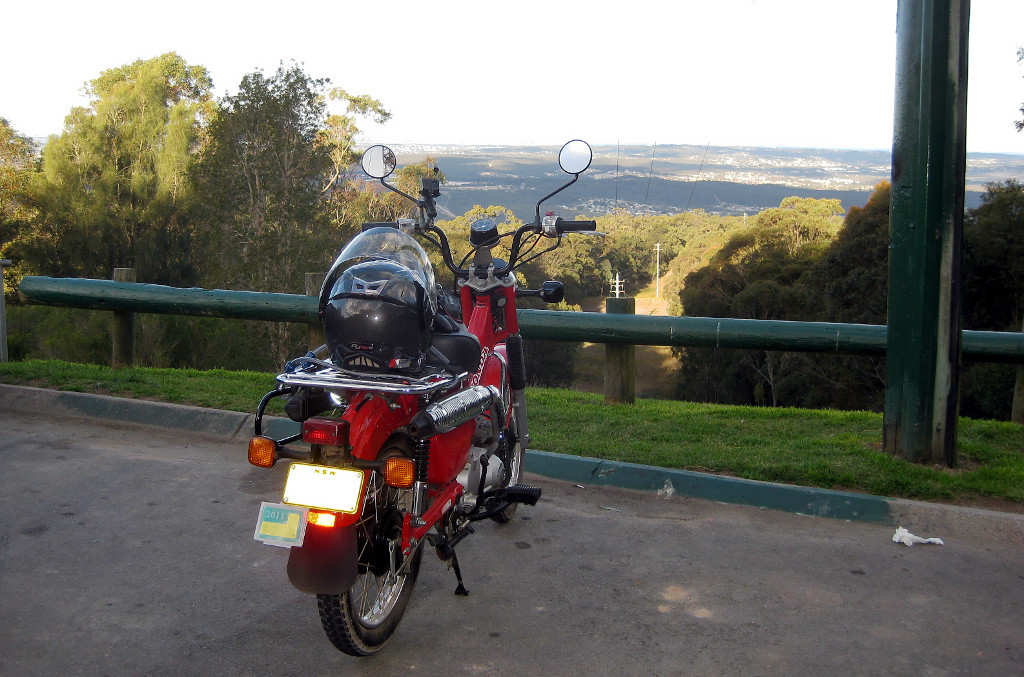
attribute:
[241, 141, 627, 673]
motorcycle — red, small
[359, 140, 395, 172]
bike mirror — round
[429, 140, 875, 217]
valley — low